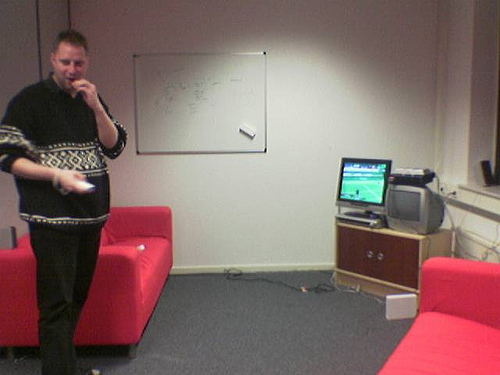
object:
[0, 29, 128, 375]
man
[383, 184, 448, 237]
televison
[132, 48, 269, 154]
white board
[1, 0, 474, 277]
wall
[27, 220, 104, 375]
pants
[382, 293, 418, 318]
wii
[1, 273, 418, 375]
floor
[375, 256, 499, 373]
couch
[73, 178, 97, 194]
controller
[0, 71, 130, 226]
sweater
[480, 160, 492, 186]
speaker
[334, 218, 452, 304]
cabinet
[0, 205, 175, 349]
couch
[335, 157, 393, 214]
monitor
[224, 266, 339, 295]
cord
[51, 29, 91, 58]
hair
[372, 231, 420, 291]
door